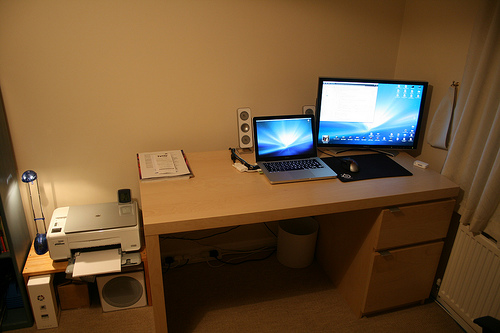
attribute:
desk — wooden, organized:
[142, 163, 463, 329]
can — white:
[271, 225, 326, 277]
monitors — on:
[248, 76, 440, 184]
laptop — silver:
[253, 115, 332, 184]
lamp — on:
[18, 167, 51, 256]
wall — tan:
[27, 11, 312, 101]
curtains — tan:
[462, 24, 489, 229]